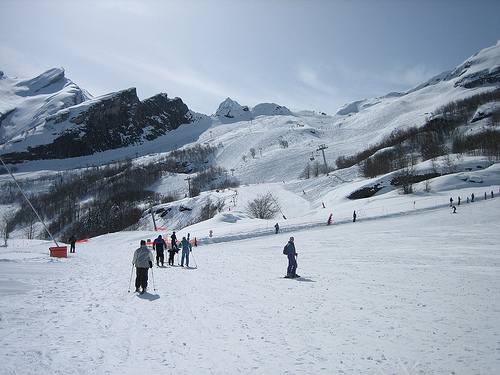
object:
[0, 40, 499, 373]
snow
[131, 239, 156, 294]
skier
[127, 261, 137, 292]
pole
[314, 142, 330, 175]
lift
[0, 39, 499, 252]
mountain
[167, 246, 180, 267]
kid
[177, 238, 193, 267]
woman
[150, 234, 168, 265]
man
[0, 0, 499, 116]
sky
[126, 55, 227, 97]
clouds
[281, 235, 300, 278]
adult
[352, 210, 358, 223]
skier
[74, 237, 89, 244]
fence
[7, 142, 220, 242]
trees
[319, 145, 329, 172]
stick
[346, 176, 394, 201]
rock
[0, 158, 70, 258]
support